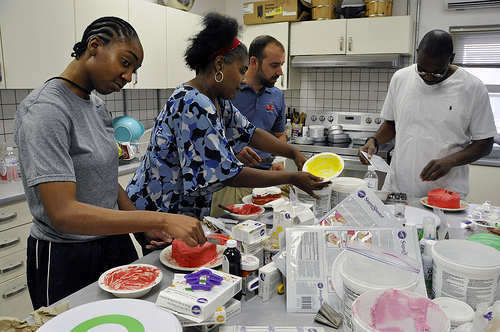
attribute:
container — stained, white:
[102, 262, 161, 294]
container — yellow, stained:
[302, 150, 346, 187]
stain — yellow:
[308, 157, 341, 176]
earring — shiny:
[213, 70, 225, 82]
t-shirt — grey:
[18, 80, 131, 239]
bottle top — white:
[226, 238, 239, 248]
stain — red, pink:
[109, 269, 155, 286]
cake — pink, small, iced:
[427, 188, 463, 210]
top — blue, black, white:
[133, 84, 254, 220]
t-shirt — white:
[370, 65, 499, 195]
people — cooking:
[25, 9, 500, 247]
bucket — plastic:
[349, 286, 450, 330]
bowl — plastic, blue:
[114, 113, 143, 142]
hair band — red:
[205, 35, 242, 57]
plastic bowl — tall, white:
[431, 238, 499, 298]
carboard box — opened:
[243, 2, 316, 23]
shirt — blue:
[228, 79, 286, 160]